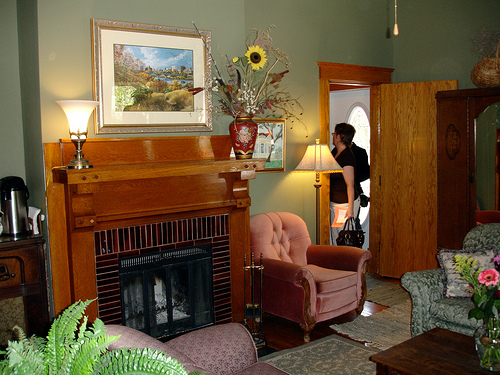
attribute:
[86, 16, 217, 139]
picture — framed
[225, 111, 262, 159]
vase — red, gold, ceramic, breakable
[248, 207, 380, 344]
chair — pink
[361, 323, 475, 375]
table — brown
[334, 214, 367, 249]
pocket book — leather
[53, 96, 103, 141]
light — lit, white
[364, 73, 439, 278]
door — open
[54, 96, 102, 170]
lamp — turned on, silver, on, brass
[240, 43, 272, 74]
sunflower — yellow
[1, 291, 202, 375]
fern — green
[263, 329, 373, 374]
rug — white, gray